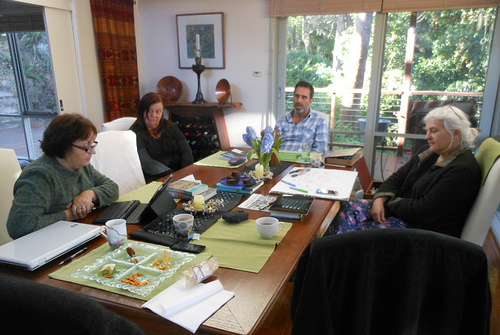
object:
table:
[0, 144, 352, 334]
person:
[3, 114, 119, 240]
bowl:
[72, 237, 197, 296]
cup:
[255, 217, 287, 238]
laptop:
[1, 217, 107, 275]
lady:
[327, 102, 484, 242]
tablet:
[268, 192, 315, 217]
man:
[267, 81, 331, 155]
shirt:
[275, 111, 330, 159]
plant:
[239, 121, 287, 177]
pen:
[289, 186, 311, 195]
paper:
[268, 164, 361, 203]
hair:
[420, 103, 478, 154]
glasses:
[66, 140, 101, 152]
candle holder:
[190, 197, 205, 211]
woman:
[127, 92, 193, 181]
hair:
[139, 91, 165, 118]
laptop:
[95, 174, 174, 225]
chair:
[100, 115, 139, 131]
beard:
[292, 102, 307, 113]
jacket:
[290, 227, 492, 334]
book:
[171, 119, 214, 148]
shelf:
[163, 95, 234, 156]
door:
[367, 0, 492, 196]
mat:
[186, 214, 293, 273]